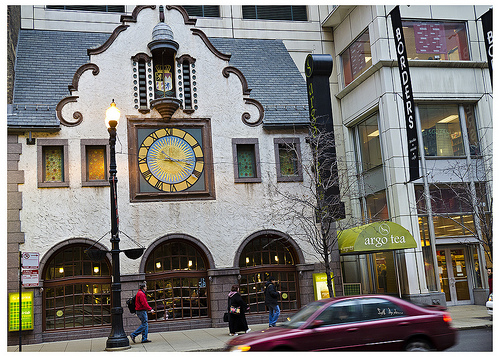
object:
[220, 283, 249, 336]
person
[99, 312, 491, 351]
street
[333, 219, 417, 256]
awning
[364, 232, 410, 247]
name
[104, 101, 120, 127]
light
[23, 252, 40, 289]
sign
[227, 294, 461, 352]
car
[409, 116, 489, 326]
trees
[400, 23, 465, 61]
windows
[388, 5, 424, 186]
banner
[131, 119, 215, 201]
clock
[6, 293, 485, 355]
sidewalk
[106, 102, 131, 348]
pole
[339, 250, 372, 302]
entrance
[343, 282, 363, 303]
brick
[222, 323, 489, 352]
road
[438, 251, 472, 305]
double doors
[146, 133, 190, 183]
yellow sun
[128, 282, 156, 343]
man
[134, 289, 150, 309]
red shirt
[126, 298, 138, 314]
black backpack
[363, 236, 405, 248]
argo tea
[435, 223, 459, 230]
light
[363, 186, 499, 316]
store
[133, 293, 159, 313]
jacket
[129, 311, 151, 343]
jeans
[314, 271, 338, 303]
sign boards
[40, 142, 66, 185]
window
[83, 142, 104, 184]
window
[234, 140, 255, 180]
window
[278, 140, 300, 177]
window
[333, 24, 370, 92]
window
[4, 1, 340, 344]
building